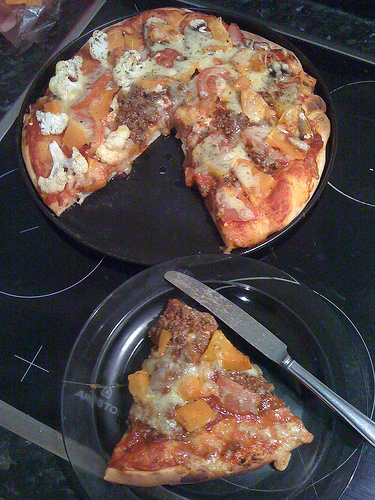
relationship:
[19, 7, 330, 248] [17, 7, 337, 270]
pizza on tray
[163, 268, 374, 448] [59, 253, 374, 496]
knife on a plate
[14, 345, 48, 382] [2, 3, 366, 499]
ex on table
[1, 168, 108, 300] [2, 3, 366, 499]
circle on table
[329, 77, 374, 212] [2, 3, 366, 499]
circle on table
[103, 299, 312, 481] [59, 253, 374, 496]
pizza on a plate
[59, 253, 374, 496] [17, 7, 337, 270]
plate near tray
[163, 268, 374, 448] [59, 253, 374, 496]
knife on plate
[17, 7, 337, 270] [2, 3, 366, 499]
tray on table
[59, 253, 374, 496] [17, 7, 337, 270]
plate in tray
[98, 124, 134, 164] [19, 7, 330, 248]
cauliflower on pizza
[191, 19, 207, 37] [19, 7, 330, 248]
mushroom on a pizza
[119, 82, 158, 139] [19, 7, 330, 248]
sausage on pizza